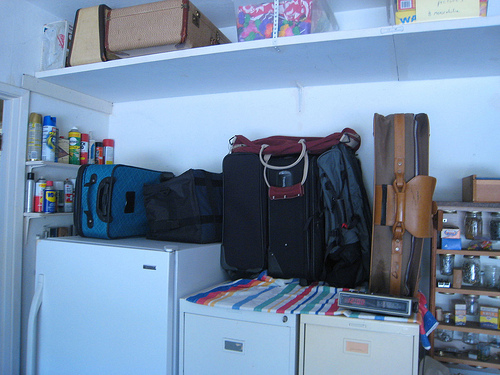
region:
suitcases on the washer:
[38, 122, 469, 297]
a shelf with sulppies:
[413, 183, 498, 373]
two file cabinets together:
[135, 283, 424, 373]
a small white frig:
[0, 233, 200, 373]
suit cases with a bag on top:
[198, 114, 395, 298]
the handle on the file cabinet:
[188, 333, 246, 371]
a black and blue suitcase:
[48, 160, 139, 253]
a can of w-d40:
[40, 174, 59, 219]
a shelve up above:
[0, 0, 488, 110]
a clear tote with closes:
[223, 0, 324, 46]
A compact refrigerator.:
[31, 232, 218, 372]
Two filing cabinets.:
[177, 273, 423, 372]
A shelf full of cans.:
[25, 110, 116, 166]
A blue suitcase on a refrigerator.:
[71, 160, 175, 239]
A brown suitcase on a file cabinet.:
[370, 108, 437, 298]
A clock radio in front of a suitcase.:
[332, 290, 414, 319]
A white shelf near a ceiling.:
[35, 16, 498, 103]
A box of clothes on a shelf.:
[225, 0, 341, 38]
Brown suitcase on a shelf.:
[102, 4, 243, 64]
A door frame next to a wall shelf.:
[1, 79, 31, 374]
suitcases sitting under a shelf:
[71, 158, 422, 300]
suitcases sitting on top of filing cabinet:
[225, 155, 387, 373]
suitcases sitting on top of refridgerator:
[79, 164, 238, 304]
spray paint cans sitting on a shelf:
[28, 134, 116, 153]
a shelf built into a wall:
[17, 149, 84, 209]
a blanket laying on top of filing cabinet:
[208, 275, 274, 339]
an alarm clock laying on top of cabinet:
[319, 291, 401, 318]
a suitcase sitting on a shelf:
[54, 15, 216, 55]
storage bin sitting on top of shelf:
[221, 7, 391, 45]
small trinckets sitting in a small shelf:
[445, 205, 498, 315]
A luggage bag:
[365, 113, 443, 300]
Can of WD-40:
[42, 178, 55, 211]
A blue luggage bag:
[74, 163, 176, 239]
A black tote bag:
[139, 170, 224, 242]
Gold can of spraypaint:
[27, 110, 42, 160]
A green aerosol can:
[67, 125, 82, 163]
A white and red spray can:
[61, 176, 74, 213]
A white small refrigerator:
[25, 235, 228, 372]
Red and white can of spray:
[33, 175, 46, 210]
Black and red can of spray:
[95, 140, 106, 163]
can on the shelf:
[27, 112, 39, 162]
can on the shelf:
[43, 113, 54, 162]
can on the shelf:
[68, 125, 83, 164]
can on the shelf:
[36, 177, 43, 217]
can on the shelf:
[43, 179, 54, 210]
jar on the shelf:
[458, 254, 480, 289]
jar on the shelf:
[463, 294, 481, 318]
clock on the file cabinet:
[334, 285, 414, 318]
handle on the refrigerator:
[18, 272, 58, 374]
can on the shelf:
[104, 139, 114, 162]